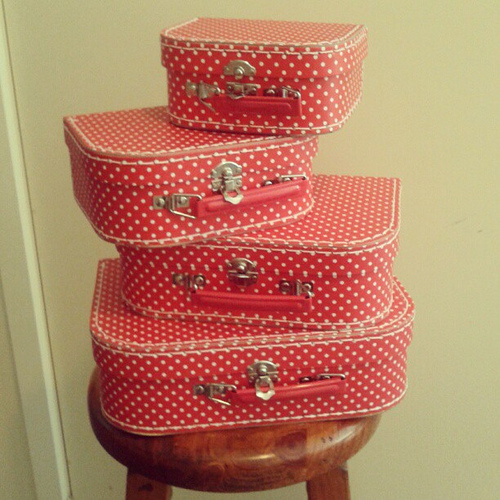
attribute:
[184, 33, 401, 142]
case — pink 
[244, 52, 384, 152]
dots — white 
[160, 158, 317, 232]
handle — pink 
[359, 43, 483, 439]
wall — white 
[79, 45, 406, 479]
luggage — white , red 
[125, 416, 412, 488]
stool — brown , wooden 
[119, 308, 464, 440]
bags — large 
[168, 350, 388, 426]
handle — red 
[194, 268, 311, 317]
handle — red 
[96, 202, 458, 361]
bag — small 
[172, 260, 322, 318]
handle — red 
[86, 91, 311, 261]
bag — tiny 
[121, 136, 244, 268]
dots — white 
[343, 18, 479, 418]
wall — beige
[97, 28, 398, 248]
luggage — red 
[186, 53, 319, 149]
luggage — silver 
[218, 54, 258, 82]
latch — metal 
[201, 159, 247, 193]
latch — metal 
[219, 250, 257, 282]
latch — metal 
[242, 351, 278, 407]
latch — metal 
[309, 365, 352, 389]
latch — metal 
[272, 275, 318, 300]
latch — metal 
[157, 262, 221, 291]
latch — metal 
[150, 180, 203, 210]
latch — metal 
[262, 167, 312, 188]
latch — metal 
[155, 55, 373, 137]
box — polka dat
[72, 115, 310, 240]
box — polka dat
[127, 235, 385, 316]
box — polka dat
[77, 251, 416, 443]
box — polka dat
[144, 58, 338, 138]
box — polka dat